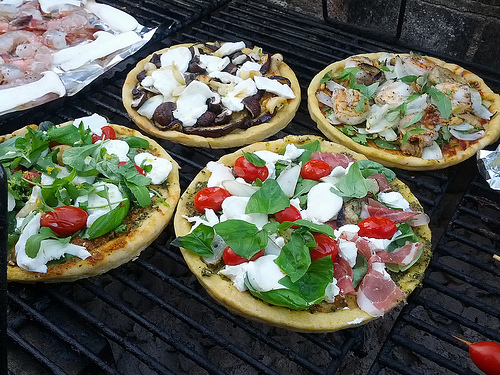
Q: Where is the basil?
A: On the two closest pizzas.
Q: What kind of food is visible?
A: Pizza.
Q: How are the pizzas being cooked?
A: On a grill.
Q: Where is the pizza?
A: On the grill.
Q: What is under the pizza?
A: A grill.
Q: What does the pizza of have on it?
A: Toppings.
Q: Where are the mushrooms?
A: On one of the pizzas.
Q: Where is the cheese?
A: On the pizzas.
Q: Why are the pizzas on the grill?
A: To cook.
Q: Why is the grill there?
A: To cook the pizzas.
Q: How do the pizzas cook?
A: Fire.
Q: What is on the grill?
A: Pizza.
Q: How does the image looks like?
A: Yummy.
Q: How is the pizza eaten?
A: Mouth.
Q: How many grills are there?
A: One.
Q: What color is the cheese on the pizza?
A: White.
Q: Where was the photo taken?
A: At a restaurant.